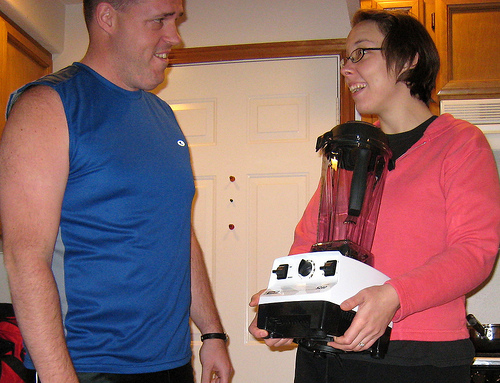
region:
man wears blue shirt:
[39, 67, 208, 379]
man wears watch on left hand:
[195, 327, 224, 346]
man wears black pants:
[55, 353, 196, 382]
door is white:
[155, 46, 325, 379]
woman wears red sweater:
[306, 133, 492, 345]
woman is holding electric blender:
[261, 119, 396, 354]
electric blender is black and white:
[258, 115, 389, 349]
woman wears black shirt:
[341, 130, 447, 188]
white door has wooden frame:
[165, 34, 395, 377]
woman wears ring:
[342, 324, 372, 359]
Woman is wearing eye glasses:
[290, 8, 469, 131]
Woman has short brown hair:
[277, 3, 492, 158]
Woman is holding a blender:
[255, 44, 427, 303]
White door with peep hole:
[207, 31, 259, 284]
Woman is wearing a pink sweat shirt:
[292, 20, 487, 221]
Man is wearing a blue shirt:
[62, 6, 219, 243]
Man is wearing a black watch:
[103, 48, 237, 360]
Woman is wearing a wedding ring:
[316, 269, 419, 371]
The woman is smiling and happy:
[272, 4, 436, 125]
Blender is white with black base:
[278, 122, 401, 346]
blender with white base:
[243, 111, 411, 358]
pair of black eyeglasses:
[330, 42, 393, 74]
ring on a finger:
[355, 335, 369, 350]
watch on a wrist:
[189, 324, 240, 350]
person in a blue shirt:
[0, 1, 235, 378]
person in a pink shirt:
[245, 6, 498, 381]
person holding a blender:
[240, 5, 498, 382]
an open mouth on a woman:
[341, 76, 376, 100]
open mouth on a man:
[146, 44, 175, 66]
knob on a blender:
[317, 258, 342, 277]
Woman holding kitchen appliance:
[240, 10, 496, 381]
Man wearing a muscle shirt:
[4, 2, 232, 378]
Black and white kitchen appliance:
[243, 125, 425, 360]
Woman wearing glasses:
[303, 1, 470, 115]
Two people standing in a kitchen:
[2, 3, 498, 368]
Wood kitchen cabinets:
[424, 1, 497, 97]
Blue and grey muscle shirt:
[10, 51, 222, 380]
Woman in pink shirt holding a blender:
[230, 9, 486, 365]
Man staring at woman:
[21, 0, 233, 372]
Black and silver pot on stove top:
[449, 298, 499, 366]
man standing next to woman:
[10, 4, 235, 379]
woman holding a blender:
[250, 11, 497, 381]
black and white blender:
[258, 122, 395, 338]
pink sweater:
[285, 114, 497, 340]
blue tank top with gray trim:
[10, 61, 195, 368]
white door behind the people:
[144, 56, 339, 377]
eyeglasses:
[342, 44, 394, 65]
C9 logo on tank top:
[176, 138, 184, 146]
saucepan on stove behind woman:
[463, 312, 498, 354]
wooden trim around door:
[160, 38, 353, 123]